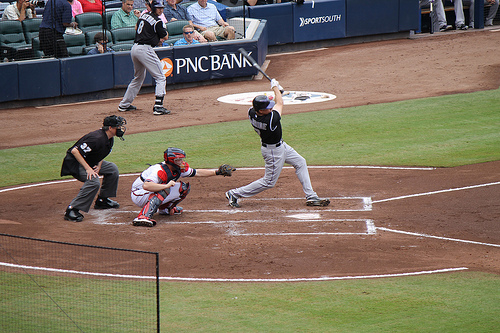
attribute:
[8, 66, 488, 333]
game — professional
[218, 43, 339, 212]
batter — Left handed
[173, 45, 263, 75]
pnc bank — behind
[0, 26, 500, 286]
dirt — brown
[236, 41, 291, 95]
bat — black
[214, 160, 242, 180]
black mitt — brown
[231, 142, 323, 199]
pants — gray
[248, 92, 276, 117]
helmet — black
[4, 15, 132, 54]
chairs — cobalt blue, comfortable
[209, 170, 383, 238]
lines — white